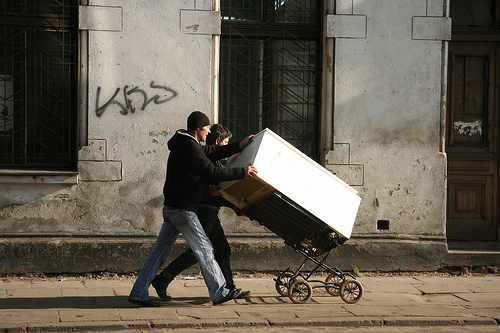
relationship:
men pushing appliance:
[126, 105, 258, 316] [214, 126, 368, 264]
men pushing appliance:
[154, 117, 251, 307] [214, 126, 368, 264]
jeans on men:
[128, 199, 234, 310] [126, 105, 258, 316]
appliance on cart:
[214, 126, 368, 264] [272, 233, 365, 308]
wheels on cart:
[339, 273, 365, 305] [272, 233, 365, 308]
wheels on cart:
[324, 269, 348, 298] [272, 233, 365, 308]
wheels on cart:
[287, 277, 316, 305] [272, 233, 365, 308]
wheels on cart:
[272, 268, 301, 299] [272, 233, 365, 308]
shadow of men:
[1, 292, 160, 314] [126, 105, 258, 316]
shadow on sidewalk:
[1, 292, 160, 314] [2, 268, 500, 328]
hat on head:
[187, 111, 211, 133] [183, 108, 212, 145]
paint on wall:
[91, 79, 179, 126] [0, 4, 459, 273]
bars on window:
[220, 4, 324, 198] [214, 1, 329, 180]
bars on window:
[3, 2, 85, 181] [1, 2, 82, 185]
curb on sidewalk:
[4, 321, 500, 332] [2, 268, 500, 328]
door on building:
[446, 34, 500, 245] [1, 1, 500, 279]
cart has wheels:
[272, 233, 365, 308] [339, 273, 365, 305]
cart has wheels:
[272, 233, 365, 308] [324, 269, 348, 298]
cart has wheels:
[272, 233, 365, 308] [272, 268, 301, 299]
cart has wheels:
[272, 233, 365, 308] [287, 277, 316, 305]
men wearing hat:
[126, 105, 258, 316] [187, 111, 211, 133]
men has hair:
[154, 117, 251, 307] [204, 123, 236, 149]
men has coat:
[126, 105, 258, 316] [159, 129, 246, 213]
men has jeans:
[126, 105, 258, 316] [128, 199, 234, 310]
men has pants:
[154, 117, 251, 307] [160, 206, 235, 298]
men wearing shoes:
[126, 105, 258, 316] [209, 285, 245, 306]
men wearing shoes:
[126, 105, 258, 316] [128, 291, 159, 313]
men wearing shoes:
[154, 117, 251, 307] [226, 283, 252, 302]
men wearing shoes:
[154, 117, 251, 307] [150, 272, 173, 301]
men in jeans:
[126, 105, 258, 316] [128, 199, 234, 310]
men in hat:
[126, 105, 258, 316] [187, 111, 211, 133]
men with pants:
[154, 117, 251, 307] [160, 206, 235, 298]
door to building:
[446, 34, 500, 245] [1, 1, 500, 279]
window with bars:
[214, 1, 329, 180] [220, 4, 324, 198]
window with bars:
[1, 2, 82, 185] [3, 2, 85, 181]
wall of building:
[0, 4, 459, 273] [1, 1, 500, 279]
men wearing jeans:
[126, 105, 258, 316] [128, 199, 234, 310]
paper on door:
[453, 117, 486, 143] [446, 34, 500, 245]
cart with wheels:
[272, 233, 365, 308] [339, 273, 365, 305]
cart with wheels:
[272, 233, 365, 308] [324, 269, 348, 298]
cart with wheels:
[272, 233, 365, 308] [272, 268, 301, 299]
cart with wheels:
[272, 233, 365, 308] [287, 277, 316, 305]